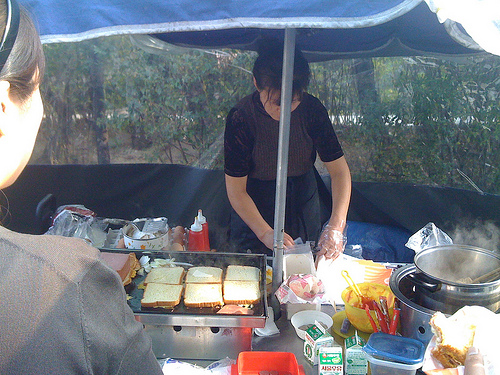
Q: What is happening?
A: They are making food.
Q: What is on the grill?
A: Bread.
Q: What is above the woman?
A: An umbrella.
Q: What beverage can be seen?
A: Milk.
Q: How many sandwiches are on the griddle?
A: Six.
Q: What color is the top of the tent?
A: Blue.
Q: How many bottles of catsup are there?
A: Two.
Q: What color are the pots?
A: Silver.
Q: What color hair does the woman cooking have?
A: Black.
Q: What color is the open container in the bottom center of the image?
A: Orange.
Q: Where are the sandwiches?
A: On the griddle.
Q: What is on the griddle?
A: Sandwiches.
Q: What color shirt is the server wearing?
A: Black.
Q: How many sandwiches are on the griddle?
A: Six.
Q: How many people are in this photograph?
A: Two.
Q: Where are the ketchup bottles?
A: Next to the griddle.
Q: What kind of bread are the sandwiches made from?
A: White bread.